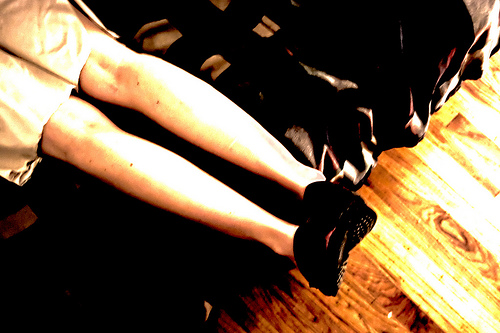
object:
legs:
[0, 53, 264, 231]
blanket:
[0, 0, 499, 333]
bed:
[1, 1, 498, 333]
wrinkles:
[35, 34, 67, 59]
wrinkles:
[78, 21, 83, 59]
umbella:
[432, 214, 481, 257]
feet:
[292, 209, 344, 297]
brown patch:
[136, 18, 184, 52]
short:
[0, 1, 117, 188]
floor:
[192, 48, 499, 332]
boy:
[0, 0, 378, 296]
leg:
[0, 0, 307, 186]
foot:
[289, 215, 351, 297]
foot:
[301, 177, 378, 252]